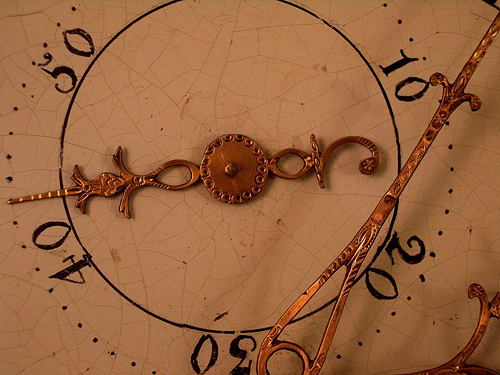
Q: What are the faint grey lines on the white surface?
A: Cracks.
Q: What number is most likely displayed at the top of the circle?
A: 60.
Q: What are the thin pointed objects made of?
A: Metal, probably brass.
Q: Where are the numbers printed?
A: Around the circle on the white background.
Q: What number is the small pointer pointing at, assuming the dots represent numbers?
A: 43.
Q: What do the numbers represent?
A: Minutes and seconds on a clock.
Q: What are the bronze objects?
A: Clock hands.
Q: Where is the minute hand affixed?
A: The center of the circle.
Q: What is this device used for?
A: To track seconds or minutes.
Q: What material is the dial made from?
A: Copper.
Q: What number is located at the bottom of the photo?
A: 30.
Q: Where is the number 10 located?
A: Upper right corner.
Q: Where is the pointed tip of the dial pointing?
A: Between 40 and 50.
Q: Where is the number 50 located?
A: Upper left corner.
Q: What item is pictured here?
A: A clock face.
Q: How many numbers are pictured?
A: 5.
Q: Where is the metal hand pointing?
A: 42.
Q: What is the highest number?
A: 50.